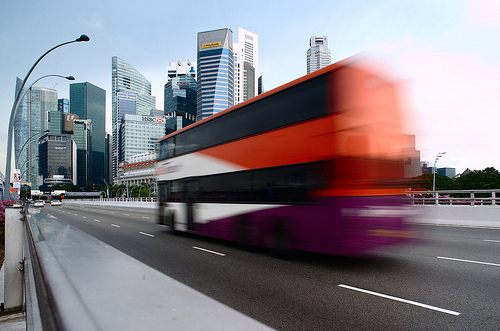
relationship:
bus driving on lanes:
[152, 47, 431, 266] [43, 200, 499, 327]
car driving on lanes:
[49, 198, 61, 210] [43, 200, 499, 327]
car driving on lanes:
[31, 199, 45, 207] [43, 200, 499, 327]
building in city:
[306, 31, 330, 74] [4, 24, 334, 205]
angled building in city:
[192, 27, 260, 120] [4, 24, 334, 205]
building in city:
[162, 56, 198, 135] [4, 24, 334, 205]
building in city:
[121, 112, 170, 167] [4, 24, 334, 205]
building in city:
[107, 52, 151, 191] [4, 24, 334, 205]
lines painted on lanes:
[40, 202, 465, 316] [43, 200, 499, 327]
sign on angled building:
[197, 38, 224, 48] [192, 27, 260, 120]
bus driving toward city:
[152, 47, 431, 266] [4, 24, 334, 205]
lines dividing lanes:
[40, 202, 465, 316] [43, 200, 499, 327]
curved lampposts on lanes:
[0, 33, 93, 201] [43, 200, 499, 327]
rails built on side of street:
[444, 200, 497, 203] [182, 174, 481, 331]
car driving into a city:
[33, 200, 44, 208] [145, 105, 253, 122]